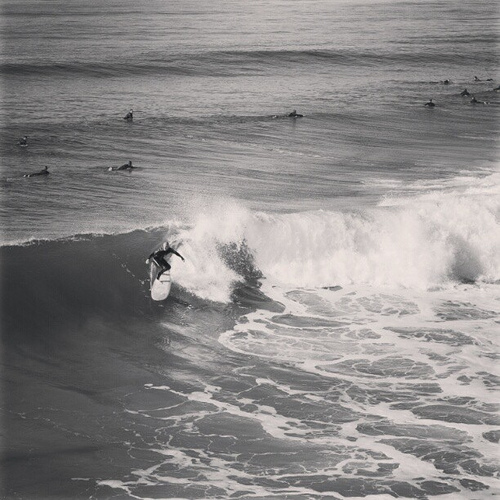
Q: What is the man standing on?
A: A surfboard.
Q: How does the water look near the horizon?
A: Calm.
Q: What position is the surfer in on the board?
A: His knees are bent.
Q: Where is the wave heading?
A: The shore.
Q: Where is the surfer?
A: In the ocean.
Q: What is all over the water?
A: Many surfers.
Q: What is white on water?
A: Waves.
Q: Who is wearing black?
A: Surfer.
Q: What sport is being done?
A: Surfing.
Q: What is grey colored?
A: The water.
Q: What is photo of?
A: Surfers in ocean.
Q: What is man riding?
A: White surfboard.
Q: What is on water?
A: White spray.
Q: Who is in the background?
A: Waves.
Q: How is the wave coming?
A: In and about to break.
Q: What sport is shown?
A: Surfing.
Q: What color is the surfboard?
A: White.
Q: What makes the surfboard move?
A: Wave.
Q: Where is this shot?
A: Ocean.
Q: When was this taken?
A: Daytime.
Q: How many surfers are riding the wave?
A: 1.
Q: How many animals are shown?
A: 0.